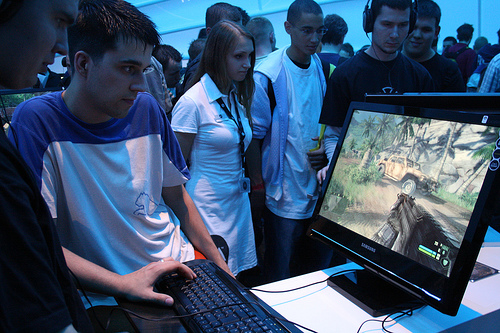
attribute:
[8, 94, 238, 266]
t-shirt — blue, white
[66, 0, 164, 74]
hair — short, brown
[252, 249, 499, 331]
whitedesk — white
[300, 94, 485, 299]
screen — computer screen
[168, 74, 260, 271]
dress — white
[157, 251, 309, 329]
keyboard — black